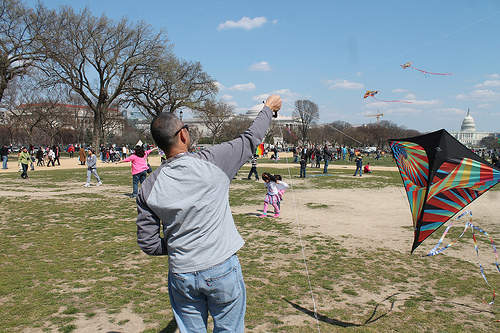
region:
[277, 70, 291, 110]
part of the sky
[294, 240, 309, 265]
rope of a kite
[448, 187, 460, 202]
part of a kite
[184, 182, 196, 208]
back of a man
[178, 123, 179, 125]
head of a man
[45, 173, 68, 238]
part of a field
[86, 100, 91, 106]
part of a building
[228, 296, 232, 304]
part of a jeans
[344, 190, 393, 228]
Tan on the ground.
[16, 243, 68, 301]
The grass is green.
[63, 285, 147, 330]
Dirt patches in the grass.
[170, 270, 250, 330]
The man is wearing jeans.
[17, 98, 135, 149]
Building in the distance.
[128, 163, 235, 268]
The shirt is grey.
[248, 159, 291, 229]
The child is playing.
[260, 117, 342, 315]
Kite string is white.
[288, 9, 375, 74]
The sky is blue.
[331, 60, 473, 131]
Kites in the sky.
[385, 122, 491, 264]
a multicoloured kite is flying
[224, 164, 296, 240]
kids are playing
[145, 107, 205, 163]
a man wearing black colour specks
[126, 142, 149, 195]
a lady is weraing pink colour t-shirt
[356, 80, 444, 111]
a kite is flying very high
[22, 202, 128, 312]
a grass with sand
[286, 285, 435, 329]
a shadow of the kite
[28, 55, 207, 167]
people standing under the tree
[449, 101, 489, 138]
a white colour building behind the tree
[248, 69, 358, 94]
a sky with clouds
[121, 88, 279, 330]
THE MAN IS FLYING A KITE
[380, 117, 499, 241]
THE KITE IS COLORFUL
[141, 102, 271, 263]
THE MAN IS WEARING A LONG SLEEVED SHIRT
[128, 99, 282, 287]
THE SHIRT IS GREY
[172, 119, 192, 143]
THE MAN IS WEARING SUNGLASSES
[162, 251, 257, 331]
THE MAN IS WEARING JEANS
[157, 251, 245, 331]
THE JEANS ARE BLUE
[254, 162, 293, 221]
THE CHILDREN ARE PLAYING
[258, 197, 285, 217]
THE GIRL IS WEARING PINK TIGHTS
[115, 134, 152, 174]
THE WOMAN IS WEARING A PINK SWEATER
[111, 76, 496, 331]
Man flying a kite.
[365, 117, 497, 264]
Multicolored kite with geometric design.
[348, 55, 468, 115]
Two kites against a blue sky.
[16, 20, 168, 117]
Tall leafless trees.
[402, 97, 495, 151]
US Capitol Building.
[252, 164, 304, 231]
Little girl playing in a park.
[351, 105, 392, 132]
Construction cane in the distance.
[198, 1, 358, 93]
Small white clouds in a blue sky.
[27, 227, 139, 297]
Patchy grass with bare spots.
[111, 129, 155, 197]
Woman with arms outstretched.